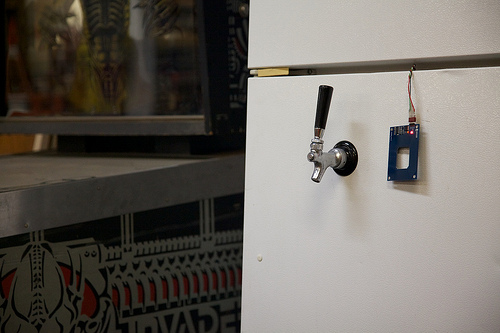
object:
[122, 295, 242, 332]
writing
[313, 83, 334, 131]
handle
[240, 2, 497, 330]
refrigerator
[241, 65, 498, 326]
door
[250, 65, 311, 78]
hinge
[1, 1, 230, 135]
frame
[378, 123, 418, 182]
item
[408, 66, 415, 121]
wires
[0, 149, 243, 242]
countertop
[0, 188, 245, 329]
pattern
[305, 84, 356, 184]
tap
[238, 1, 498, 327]
front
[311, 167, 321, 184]
nozzle